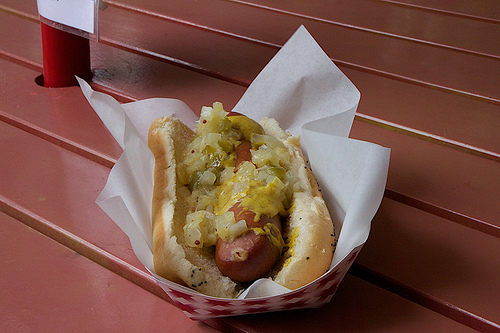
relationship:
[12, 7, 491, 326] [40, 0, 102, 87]
table has pole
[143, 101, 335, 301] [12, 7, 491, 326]
bun on table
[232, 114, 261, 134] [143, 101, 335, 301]
mustard on bun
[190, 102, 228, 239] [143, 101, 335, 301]
onions on bun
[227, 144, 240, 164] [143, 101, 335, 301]
relish on bun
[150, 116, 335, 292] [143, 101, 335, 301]
bun on bun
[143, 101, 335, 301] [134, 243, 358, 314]
bun on tray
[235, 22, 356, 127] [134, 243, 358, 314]
paper on tray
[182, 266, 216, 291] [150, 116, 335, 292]
seeds on bun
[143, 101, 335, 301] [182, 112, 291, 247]
bun has toppings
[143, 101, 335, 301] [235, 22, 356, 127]
bun on paper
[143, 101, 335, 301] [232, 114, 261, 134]
bun with mustard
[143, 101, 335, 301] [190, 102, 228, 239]
bun with onions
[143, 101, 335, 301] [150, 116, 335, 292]
bun on bun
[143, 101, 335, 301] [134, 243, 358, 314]
bun in tray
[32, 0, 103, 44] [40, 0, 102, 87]
sign on pole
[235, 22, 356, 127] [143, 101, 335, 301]
paper under bun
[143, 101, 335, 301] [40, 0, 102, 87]
bun near pole